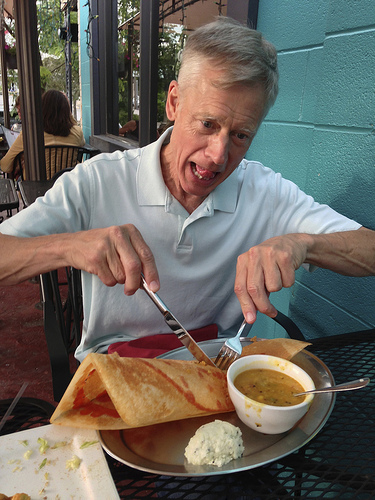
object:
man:
[0, 14, 374, 364]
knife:
[139, 272, 218, 369]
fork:
[213, 318, 248, 372]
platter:
[89, 336, 337, 476]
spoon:
[293, 377, 370, 398]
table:
[2, 327, 375, 499]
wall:
[216, 0, 374, 342]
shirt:
[0, 124, 363, 364]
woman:
[0, 89, 85, 182]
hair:
[175, 14, 279, 121]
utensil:
[293, 376, 371, 398]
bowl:
[227, 354, 317, 435]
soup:
[234, 369, 307, 407]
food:
[48, 337, 314, 431]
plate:
[0, 423, 120, 499]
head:
[164, 14, 280, 198]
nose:
[204, 124, 231, 166]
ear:
[165, 79, 178, 121]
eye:
[199, 117, 214, 131]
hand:
[71, 223, 161, 297]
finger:
[115, 233, 142, 297]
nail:
[149, 281, 160, 293]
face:
[178, 74, 262, 198]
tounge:
[196, 165, 214, 179]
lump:
[184, 419, 245, 467]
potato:
[183, 419, 246, 468]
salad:
[182, 420, 244, 469]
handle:
[293, 377, 370, 397]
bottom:
[213, 337, 242, 376]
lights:
[79, 4, 139, 130]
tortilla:
[48, 337, 312, 431]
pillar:
[12, 2, 47, 182]